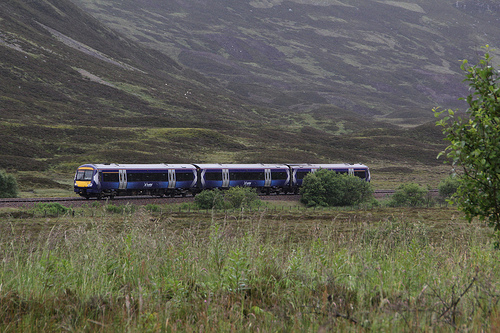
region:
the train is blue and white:
[77, 143, 391, 216]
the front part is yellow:
[74, 162, 96, 189]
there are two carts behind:
[197, 148, 378, 190]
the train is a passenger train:
[82, 157, 382, 212]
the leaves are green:
[459, 103, 498, 211]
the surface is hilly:
[163, 28, 462, 134]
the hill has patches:
[225, 32, 408, 92]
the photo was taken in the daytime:
[4, 14, 497, 299]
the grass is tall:
[100, 208, 425, 288]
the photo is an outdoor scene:
[4, 98, 498, 304]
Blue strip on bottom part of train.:
[109, 166, 280, 198]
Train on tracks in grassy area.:
[41, 147, 435, 176]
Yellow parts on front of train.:
[71, 162, 115, 215]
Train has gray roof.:
[96, 145, 369, 183]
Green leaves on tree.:
[445, 118, 466, 144]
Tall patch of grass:
[83, 211, 463, 328]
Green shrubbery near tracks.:
[177, 180, 411, 220]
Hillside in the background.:
[70, 100, 349, 156]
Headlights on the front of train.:
[61, 176, 113, 207]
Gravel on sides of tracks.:
[22, 161, 192, 220]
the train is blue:
[65, 151, 393, 197]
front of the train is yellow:
[65, 162, 100, 197]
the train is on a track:
[71, 182, 396, 204]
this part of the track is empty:
[363, 172, 468, 200]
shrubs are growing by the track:
[7, 197, 190, 223]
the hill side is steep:
[65, 12, 460, 144]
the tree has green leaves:
[411, 55, 496, 244]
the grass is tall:
[7, 227, 485, 332]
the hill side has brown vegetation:
[14, 80, 140, 145]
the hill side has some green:
[136, 123, 231, 160]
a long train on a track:
[47, 122, 390, 214]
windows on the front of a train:
[66, 151, 101, 203]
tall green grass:
[6, 240, 473, 307]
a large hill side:
[1, 0, 468, 172]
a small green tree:
[412, 38, 492, 243]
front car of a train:
[60, 157, 202, 206]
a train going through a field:
[0, 58, 452, 267]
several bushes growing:
[188, 165, 476, 222]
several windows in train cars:
[96, 161, 368, 189]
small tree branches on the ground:
[397, 257, 489, 331]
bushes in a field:
[194, 185, 260, 212]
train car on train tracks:
[67, 156, 199, 201]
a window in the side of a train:
[99, 170, 126, 187]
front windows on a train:
[70, 165, 98, 190]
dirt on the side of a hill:
[156, 29, 207, 63]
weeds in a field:
[191, 237, 256, 295]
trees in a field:
[436, 71, 498, 221]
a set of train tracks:
[5, 194, 70, 213]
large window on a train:
[122, 169, 174, 187]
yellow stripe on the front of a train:
[71, 179, 96, 191]